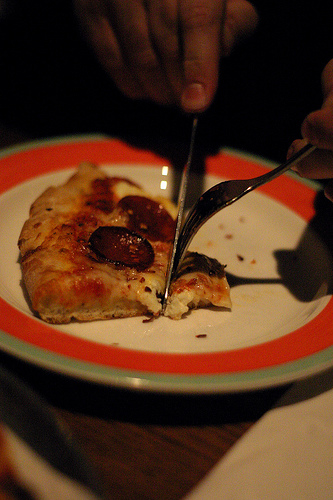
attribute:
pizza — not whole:
[17, 162, 231, 323]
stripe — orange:
[0, 295, 332, 373]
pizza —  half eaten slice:
[83, 192, 143, 226]